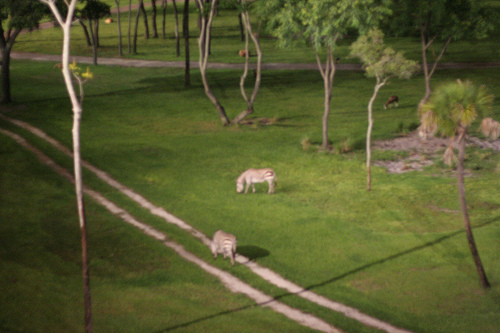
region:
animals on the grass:
[158, 145, 303, 302]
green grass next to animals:
[159, 141, 208, 185]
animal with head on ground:
[219, 147, 283, 206]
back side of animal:
[221, 229, 248, 262]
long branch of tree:
[34, 198, 119, 292]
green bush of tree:
[338, 37, 410, 110]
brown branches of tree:
[180, 41, 287, 122]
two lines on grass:
[108, 173, 189, 270]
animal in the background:
[376, 87, 406, 122]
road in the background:
[116, 38, 166, 93]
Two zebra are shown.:
[182, 160, 323, 267]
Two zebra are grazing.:
[182, 153, 309, 275]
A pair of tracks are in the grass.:
[89, 152, 189, 282]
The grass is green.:
[316, 183, 358, 240]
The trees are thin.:
[178, 8, 389, 150]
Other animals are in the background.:
[100, 10, 421, 137]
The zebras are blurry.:
[154, 152, 324, 269]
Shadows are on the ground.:
[90, 54, 252, 124]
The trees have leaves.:
[244, 0, 439, 105]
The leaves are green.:
[253, 1, 427, 90]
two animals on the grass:
[193, 146, 300, 272]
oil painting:
[1, 2, 491, 332]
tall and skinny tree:
[351, 31, 386, 194]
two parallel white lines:
[13, 116, 399, 332]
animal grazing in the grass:
[225, 159, 281, 199]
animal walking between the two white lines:
[193, 216, 242, 282]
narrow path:
[13, 43, 343, 79]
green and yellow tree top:
[416, 79, 498, 166]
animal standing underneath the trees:
[381, 92, 403, 112]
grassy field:
[8, 56, 488, 331]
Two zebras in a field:
[188, 152, 305, 270]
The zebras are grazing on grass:
[193, 161, 278, 293]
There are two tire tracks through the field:
[23, 95, 361, 330]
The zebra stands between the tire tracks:
[183, 205, 254, 263]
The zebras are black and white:
[193, 147, 305, 269]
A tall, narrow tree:
[48, 15, 118, 320]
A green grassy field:
[30, 59, 429, 309]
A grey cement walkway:
[38, 44, 440, 90]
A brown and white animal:
[379, 82, 404, 120]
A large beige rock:
[227, 41, 262, 69]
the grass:
[150, 169, 371, 329]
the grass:
[243, 155, 415, 319]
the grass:
[290, 210, 335, 258]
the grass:
[310, 200, 357, 312]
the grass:
[300, 205, 343, 295]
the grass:
[298, 246, 362, 297]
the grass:
[298, 210, 390, 320]